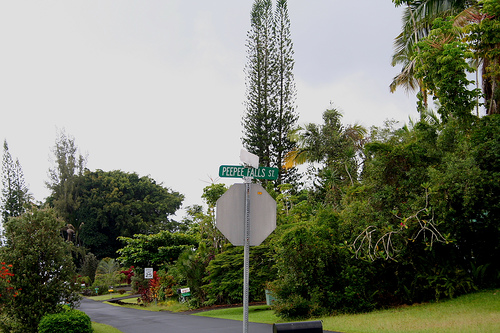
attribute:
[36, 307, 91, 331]
bush — green 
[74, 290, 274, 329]
road — black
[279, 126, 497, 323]
bushes — green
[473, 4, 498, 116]
palm tree — green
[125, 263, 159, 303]
plant — red 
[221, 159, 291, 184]
sign — green 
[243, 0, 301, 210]
tree — tall , thin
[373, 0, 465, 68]
leaves — palm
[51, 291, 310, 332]
road — paved 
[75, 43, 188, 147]
sky — cloudy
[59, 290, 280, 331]
road — gray 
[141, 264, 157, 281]
sign — metal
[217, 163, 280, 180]
sign — green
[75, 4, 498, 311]
forest — tree filled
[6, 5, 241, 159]
sky — blue , cloudy 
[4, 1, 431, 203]
sky — overcast, blue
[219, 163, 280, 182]
street sign — metal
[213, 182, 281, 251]
street sign — metal